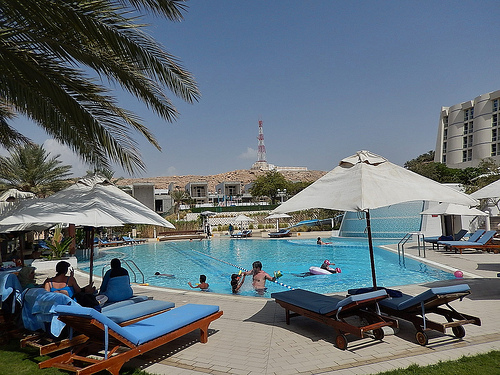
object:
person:
[241, 261, 283, 293]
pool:
[79, 234, 469, 301]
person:
[230, 274, 245, 295]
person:
[185, 275, 212, 293]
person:
[301, 260, 340, 275]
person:
[155, 270, 179, 282]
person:
[316, 236, 334, 246]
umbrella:
[270, 152, 478, 339]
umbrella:
[0, 177, 175, 297]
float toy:
[309, 265, 336, 278]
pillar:
[252, 114, 271, 173]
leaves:
[0, 0, 182, 134]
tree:
[0, 0, 203, 176]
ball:
[455, 270, 464, 280]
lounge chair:
[272, 289, 390, 349]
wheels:
[333, 332, 349, 350]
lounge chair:
[347, 284, 481, 346]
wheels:
[416, 328, 430, 349]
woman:
[45, 262, 82, 298]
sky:
[1, 0, 499, 182]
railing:
[398, 233, 426, 269]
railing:
[102, 259, 146, 285]